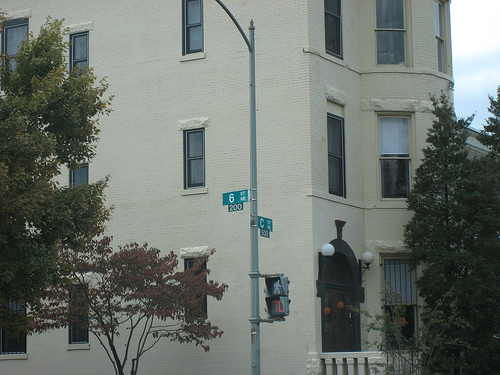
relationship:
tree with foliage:
[26, 238, 228, 373] [26, 245, 228, 352]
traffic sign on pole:
[259, 267, 299, 317] [237, 11, 271, 372]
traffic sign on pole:
[259, 267, 299, 317] [228, 44, 268, 369]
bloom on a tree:
[200, 344, 212, 354] [33, 242, 224, 369]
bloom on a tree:
[217, 281, 227, 293] [33, 242, 224, 369]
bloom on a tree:
[130, 241, 142, 249] [33, 242, 224, 369]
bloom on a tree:
[112, 329, 119, 336] [33, 242, 224, 369]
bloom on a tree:
[42, 322, 54, 330] [33, 242, 224, 369]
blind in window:
[372, 110, 416, 160] [358, 92, 441, 233]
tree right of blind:
[400, 99, 484, 373] [364, 102, 422, 217]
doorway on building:
[312, 238, 372, 354] [0, 0, 500, 373]